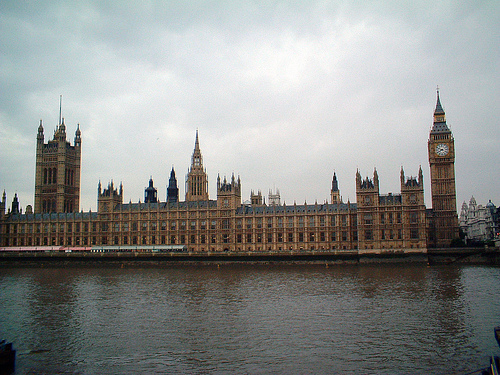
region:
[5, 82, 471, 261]
the houses of Parliament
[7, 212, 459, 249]
windows in the side of the building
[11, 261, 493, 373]
gentle waves in the river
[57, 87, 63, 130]
pinnacle sticking up the tower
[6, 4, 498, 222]
broken clouds in the sky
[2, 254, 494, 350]
the building's reflection in the water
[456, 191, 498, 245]
this building is white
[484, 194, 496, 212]
a dome in the background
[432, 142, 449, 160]
the clock face is white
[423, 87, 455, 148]
the trim is dark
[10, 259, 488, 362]
the river Thames in front of Parliament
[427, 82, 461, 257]
the clock tower across the river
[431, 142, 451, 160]
the clock on the clock tower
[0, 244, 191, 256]
canopies in front of the building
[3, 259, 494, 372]
the river is blue and brown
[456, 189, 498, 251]
white buildings in the distance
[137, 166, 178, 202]
these towers are dark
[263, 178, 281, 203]
this tower is white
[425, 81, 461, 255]
the clock tower is tall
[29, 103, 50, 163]
This is a tower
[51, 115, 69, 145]
This is a tower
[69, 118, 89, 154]
This is a tower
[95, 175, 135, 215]
This is a tower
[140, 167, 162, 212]
This is a tower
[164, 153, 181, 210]
This is a tower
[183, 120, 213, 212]
This is a tower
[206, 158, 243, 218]
This is a tower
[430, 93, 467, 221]
This is a tower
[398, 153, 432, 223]
This is a tower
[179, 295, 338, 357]
small ripples on surface of water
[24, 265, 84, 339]
reflection of building on water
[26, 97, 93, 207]
brown stone building tower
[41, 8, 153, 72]
large white cloud in sky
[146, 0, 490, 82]
hazy cloud filled sky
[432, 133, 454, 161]
large white clock face on tower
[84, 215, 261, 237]
row of windows on side of building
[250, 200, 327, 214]
grey shingles on building roof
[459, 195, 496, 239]
large white stone building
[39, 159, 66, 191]
windows on side of stone tower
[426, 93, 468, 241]
the Big Ben tower next to a large building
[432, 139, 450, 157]
the clock in the tower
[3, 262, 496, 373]
the river right next to the building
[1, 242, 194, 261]
a train going down the track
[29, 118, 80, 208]
another tall building in the background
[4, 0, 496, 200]
the bright sunny sky with some clouds in it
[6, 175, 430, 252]
a large fancy building to the left of the Big Ben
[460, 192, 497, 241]
another fancy building in the town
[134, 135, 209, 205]
a few more tall buildings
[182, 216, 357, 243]
some windows in the building